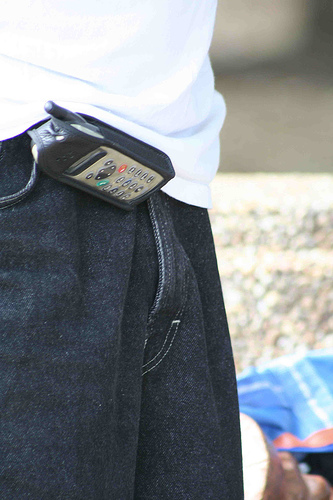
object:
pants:
[5, 126, 244, 498]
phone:
[31, 99, 176, 208]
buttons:
[147, 176, 155, 183]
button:
[119, 164, 128, 173]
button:
[97, 180, 110, 187]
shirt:
[0, 1, 227, 211]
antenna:
[44, 100, 86, 121]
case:
[31, 100, 176, 208]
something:
[224, 352, 333, 466]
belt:
[10, 126, 29, 150]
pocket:
[0, 144, 47, 214]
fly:
[146, 198, 180, 326]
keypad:
[78, 157, 157, 199]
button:
[115, 176, 125, 184]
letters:
[118, 178, 124, 184]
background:
[215, 0, 331, 374]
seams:
[141, 314, 180, 382]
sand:
[204, 171, 332, 340]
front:
[65, 151, 159, 205]